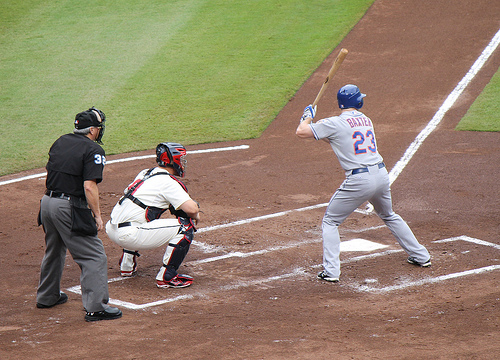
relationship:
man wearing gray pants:
[29, 104, 132, 326] [36, 185, 115, 320]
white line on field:
[209, 138, 254, 159] [2, 2, 500, 351]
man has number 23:
[294, 47, 433, 282] [300, 47, 434, 282]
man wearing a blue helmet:
[294, 45, 433, 275] [337, 79, 371, 111]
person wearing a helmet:
[294, 45, 433, 275] [337, 79, 371, 111]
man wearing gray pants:
[34, 106, 121, 322] [36, 185, 115, 320]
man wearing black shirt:
[34, 106, 121, 322] [41, 132, 106, 204]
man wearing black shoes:
[29, 104, 132, 326] [35, 284, 124, 324]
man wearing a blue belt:
[294, 45, 433, 275] [343, 165, 374, 175]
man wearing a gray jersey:
[294, 45, 433, 275] [306, 109, 383, 169]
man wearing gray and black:
[29, 104, 132, 326] [61, 171, 68, 216]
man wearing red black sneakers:
[102, 141, 205, 301] [155, 272, 197, 290]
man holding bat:
[294, 45, 433, 275] [294, 46, 351, 137]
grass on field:
[0, 1, 292, 82] [2, 2, 500, 351]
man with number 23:
[294, 45, 433, 275] [349, 127, 380, 157]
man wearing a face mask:
[34, 106, 121, 322] [89, 105, 109, 145]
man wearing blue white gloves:
[294, 45, 433, 275] [297, 105, 321, 119]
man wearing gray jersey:
[294, 45, 433, 275] [311, 109, 392, 169]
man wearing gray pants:
[294, 45, 433, 275] [330, 168, 407, 250]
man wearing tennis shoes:
[294, 45, 433, 275] [305, 257, 343, 292]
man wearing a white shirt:
[102, 141, 205, 301] [118, 164, 187, 226]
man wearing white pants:
[102, 141, 205, 301] [110, 221, 184, 268]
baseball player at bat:
[294, 45, 433, 275] [294, 46, 351, 137]